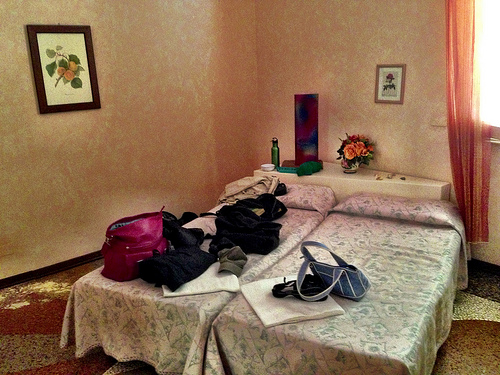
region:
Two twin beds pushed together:
[78, 156, 476, 365]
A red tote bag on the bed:
[82, 201, 184, 287]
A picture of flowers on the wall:
[5, 24, 102, 122]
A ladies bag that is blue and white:
[274, 232, 379, 319]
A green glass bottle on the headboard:
[268, 134, 285, 170]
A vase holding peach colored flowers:
[338, 124, 368, 174]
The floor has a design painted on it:
[1, 281, 57, 365]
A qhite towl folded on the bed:
[246, 273, 368, 338]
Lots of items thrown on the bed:
[67, 163, 277, 310]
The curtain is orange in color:
[432, 33, 490, 245]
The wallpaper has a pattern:
[107, 39, 194, 121]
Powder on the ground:
[2, 281, 66, 307]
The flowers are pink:
[337, 134, 372, 171]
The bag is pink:
[102, 209, 168, 283]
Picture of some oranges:
[44, 41, 86, 91]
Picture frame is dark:
[25, 24, 100, 111]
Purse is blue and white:
[295, 240, 367, 302]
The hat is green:
[216, 244, 247, 274]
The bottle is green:
[271, 137, 279, 165]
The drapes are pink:
[443, 1, 489, 239]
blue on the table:
[285, 234, 396, 304]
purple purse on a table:
[97, 198, 177, 280]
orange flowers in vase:
[335, 123, 370, 176]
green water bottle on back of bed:
[269, 130, 281, 165]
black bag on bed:
[209, 192, 290, 259]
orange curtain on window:
[440, 43, 494, 252]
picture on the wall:
[375, 64, 407, 111]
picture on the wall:
[25, 43, 102, 110]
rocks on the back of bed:
[372, 163, 416, 184]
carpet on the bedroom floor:
[9, 293, 60, 369]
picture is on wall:
[22, 14, 126, 141]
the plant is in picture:
[20, 20, 122, 140]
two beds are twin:
[193, 157, 440, 374]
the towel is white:
[246, 265, 346, 345]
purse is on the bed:
[298, 228, 405, 320]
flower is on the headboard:
[314, 117, 459, 202]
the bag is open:
[99, 210, 210, 306]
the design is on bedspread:
[368, 222, 430, 339]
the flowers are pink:
[342, 127, 389, 169]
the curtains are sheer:
[435, 62, 498, 240]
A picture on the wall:
[373, 61, 404, 106]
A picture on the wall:
[23, 23, 101, 115]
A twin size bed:
[218, 195, 464, 373]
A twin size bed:
[73, 184, 334, 361]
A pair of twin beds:
[70, 175, 467, 374]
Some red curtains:
[444, 1, 493, 246]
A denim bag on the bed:
[295, 238, 370, 304]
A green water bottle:
[269, 136, 281, 167]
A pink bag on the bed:
[98, 203, 165, 281]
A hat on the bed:
[216, 245, 249, 277]